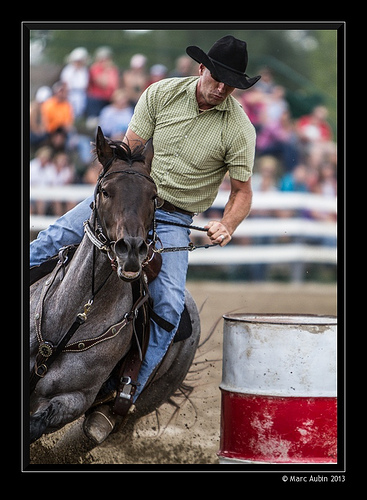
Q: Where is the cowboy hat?
A: On the man's head.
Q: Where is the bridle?
A: On the horse's head.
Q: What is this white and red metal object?
A: Steel barrel.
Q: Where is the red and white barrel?
A: In the lower right corner.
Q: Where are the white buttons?
A: On the shirt.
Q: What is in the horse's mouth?
A: Bit.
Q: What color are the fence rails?
A: White.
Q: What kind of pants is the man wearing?
A: Blue jeans.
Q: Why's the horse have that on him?
A: It's a harness.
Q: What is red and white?
A: The barrel.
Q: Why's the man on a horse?
A: He's rising if.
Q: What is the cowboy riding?
A: A horse.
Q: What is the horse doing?
A: Running.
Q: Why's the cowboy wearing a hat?
A: That's what Cowboys do.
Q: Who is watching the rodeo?
A: Patrons.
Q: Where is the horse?
A: Running around.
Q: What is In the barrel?
A: Water.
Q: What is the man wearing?
A: Blue jeans.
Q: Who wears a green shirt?
A: Cowboy.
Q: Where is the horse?
A: In the arena.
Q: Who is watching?
A: Spectators.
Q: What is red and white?
A: The barrel.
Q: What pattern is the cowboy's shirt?
A: Checked.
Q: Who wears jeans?
A: The cowboy.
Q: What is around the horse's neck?
A: Harness.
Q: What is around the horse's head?
A: Harness.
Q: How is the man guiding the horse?
A: With reins.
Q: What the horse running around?
A: A barrel.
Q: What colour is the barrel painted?
A: Red and white.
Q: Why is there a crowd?
A: To watch the man ride the horse.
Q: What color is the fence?
A: White.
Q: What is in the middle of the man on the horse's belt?
A: A buckle.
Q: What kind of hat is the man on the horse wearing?
A: A cowboy hat.